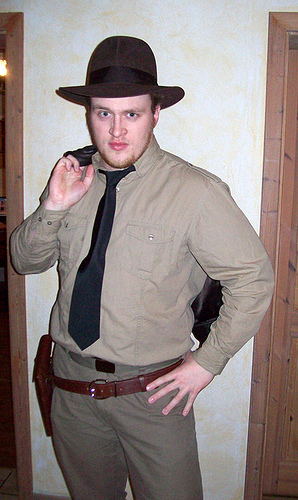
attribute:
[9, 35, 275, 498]
man — sheriff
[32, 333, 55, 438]
holster — brown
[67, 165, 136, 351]
tie — black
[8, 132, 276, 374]
shirt — khaki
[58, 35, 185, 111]
cowboy hat — brown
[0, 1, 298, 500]
wall — white